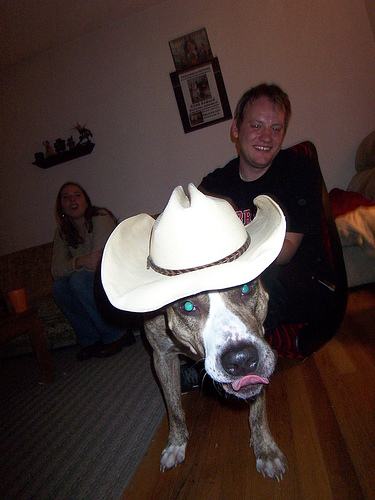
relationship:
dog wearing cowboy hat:
[97, 179, 292, 488] [96, 180, 290, 317]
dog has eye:
[97, 179, 292, 488] [174, 301, 201, 320]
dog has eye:
[97, 179, 292, 488] [237, 282, 252, 297]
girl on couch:
[48, 176, 139, 367] [1, 213, 172, 371]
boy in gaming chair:
[170, 76, 324, 400] [206, 138, 353, 391]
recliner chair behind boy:
[324, 127, 373, 297] [170, 76, 324, 400]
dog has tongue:
[97, 179, 292, 488] [228, 375, 274, 395]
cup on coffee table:
[4, 284, 33, 320] [1, 304, 59, 382]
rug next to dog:
[2, 332, 173, 496] [97, 179, 292, 488]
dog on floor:
[97, 179, 292, 488] [118, 277, 374, 499]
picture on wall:
[160, 21, 215, 72] [1, 0, 375, 258]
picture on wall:
[165, 51, 235, 140] [1, 0, 375, 258]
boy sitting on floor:
[170, 76, 324, 400] [118, 277, 374, 499]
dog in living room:
[97, 179, 292, 488] [1, 0, 373, 499]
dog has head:
[97, 179, 292, 488] [95, 175, 289, 405]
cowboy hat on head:
[96, 180, 290, 317] [95, 175, 289, 405]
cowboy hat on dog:
[96, 180, 290, 317] [97, 179, 292, 488]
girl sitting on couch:
[48, 176, 139, 367] [1, 213, 172, 371]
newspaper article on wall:
[170, 53, 234, 137] [1, 0, 375, 258]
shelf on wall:
[26, 138, 104, 176] [1, 0, 375, 258]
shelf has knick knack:
[26, 138, 104, 176] [70, 120, 97, 147]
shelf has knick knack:
[26, 138, 104, 176] [64, 134, 82, 154]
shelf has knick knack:
[26, 138, 104, 176] [49, 135, 71, 160]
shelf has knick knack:
[26, 138, 104, 176] [40, 137, 60, 163]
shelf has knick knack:
[26, 138, 104, 176] [29, 148, 49, 165]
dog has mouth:
[97, 179, 292, 488] [211, 357, 278, 407]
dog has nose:
[97, 179, 292, 488] [215, 337, 262, 380]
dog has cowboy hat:
[97, 179, 292, 488] [96, 180, 290, 317]